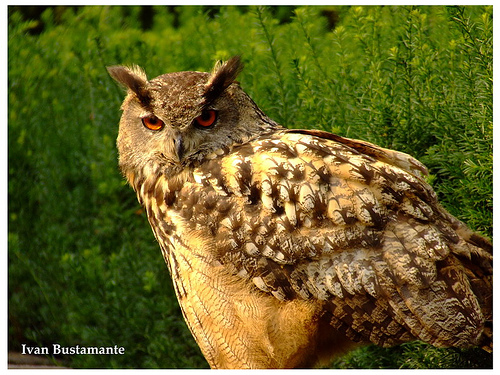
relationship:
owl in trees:
[104, 51, 491, 369] [83, 32, 471, 351]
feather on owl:
[365, 222, 442, 290] [104, 51, 491, 369]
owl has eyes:
[104, 51, 491, 369] [137, 104, 220, 133]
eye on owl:
[191, 105, 219, 130] [104, 51, 491, 369]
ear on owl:
[211, 50, 263, 101] [107, 33, 387, 373]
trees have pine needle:
[293, 19, 498, 139] [385, 50, 405, 81]